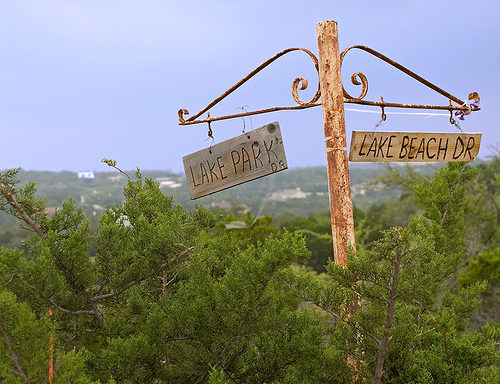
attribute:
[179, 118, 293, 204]
street sign — wooden, lake park dr, hanging down, long, wood, homemade, rectangular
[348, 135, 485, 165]
street sign — wooden, lake beach dr, lakebeach dr, hanging down, long, homemade, rectangular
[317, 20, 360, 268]
pole — rusted, wooden, rusty, brown, white, rusting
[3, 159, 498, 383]
branches — evergreen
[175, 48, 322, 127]
rod — rusted, metal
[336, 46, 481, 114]
rod — rusted, metal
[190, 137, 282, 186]
name of street — craved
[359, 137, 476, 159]
name of street — craved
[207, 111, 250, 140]
wire — metal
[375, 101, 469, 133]
wire — metal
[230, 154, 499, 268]
trees — lush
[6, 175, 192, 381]
tree — brown, pine, green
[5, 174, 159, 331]
leaves — green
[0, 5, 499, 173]
sky — blue, clear, cloudless